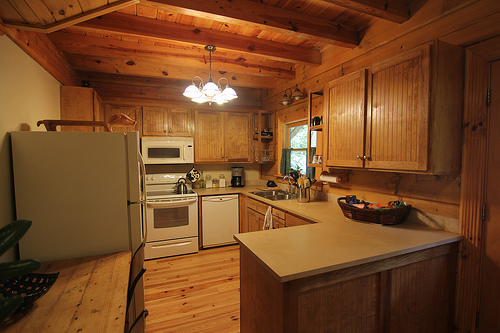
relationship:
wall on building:
[4, 66, 71, 131] [5, 101, 494, 333]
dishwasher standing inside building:
[200, 192, 240, 250] [0, 0, 499, 332]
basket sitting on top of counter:
[339, 190, 411, 227] [231, 186, 470, 333]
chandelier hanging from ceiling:
[180, 43, 240, 106] [2, 1, 472, 114]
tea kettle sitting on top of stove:
[172, 176, 188, 195] [141, 170, 201, 260]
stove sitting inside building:
[140, 163, 200, 263] [0, 0, 499, 332]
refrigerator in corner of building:
[6, 122, 155, 272] [0, 0, 499, 332]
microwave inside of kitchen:
[141, 129, 201, 166] [33, 35, 477, 329]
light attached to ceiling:
[180, 81, 245, 106] [51, 9, 346, 101]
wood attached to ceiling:
[57, 16, 288, 81] [22, 5, 395, 84]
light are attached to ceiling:
[197, 80, 221, 100] [22, 2, 365, 90]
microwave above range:
[139, 135, 197, 166] [145, 167, 196, 261]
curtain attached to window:
[279, 139, 329, 175] [270, 112, 316, 179]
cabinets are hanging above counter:
[314, 60, 442, 171] [245, 159, 465, 294]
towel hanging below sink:
[253, 201, 283, 234] [249, 169, 308, 207]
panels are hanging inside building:
[322, 169, 450, 205] [0, 0, 499, 332]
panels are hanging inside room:
[316, 19, 486, 55] [9, 6, 485, 332]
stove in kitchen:
[150, 159, 197, 261] [100, 93, 460, 322]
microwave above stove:
[139, 135, 197, 166] [140, 163, 200, 263]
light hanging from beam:
[197, 80, 221, 100] [58, 16, 319, 78]